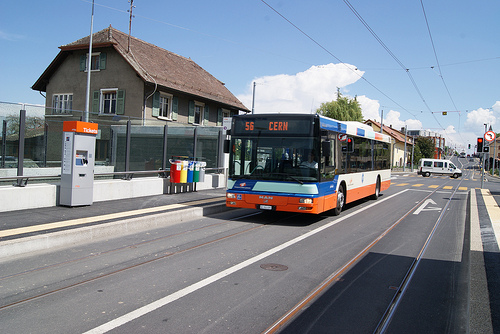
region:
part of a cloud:
[304, 50, 339, 92]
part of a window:
[277, 143, 292, 166]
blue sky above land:
[211, 13, 253, 50]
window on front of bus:
[228, 134, 325, 189]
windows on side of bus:
[336, 135, 394, 171]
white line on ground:
[222, 235, 299, 288]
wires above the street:
[323, 38, 458, 98]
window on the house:
[93, 78, 135, 122]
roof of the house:
[153, 65, 204, 87]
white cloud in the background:
[280, 68, 332, 95]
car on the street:
[411, 148, 467, 193]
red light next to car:
[469, 131, 494, 159]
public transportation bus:
[222, 81, 394, 216]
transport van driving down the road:
[412, 148, 466, 180]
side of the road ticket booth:
[61, 116, 103, 210]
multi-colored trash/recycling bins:
[167, 150, 210, 192]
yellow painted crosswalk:
[396, 178, 484, 193]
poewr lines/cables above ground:
[267, 3, 476, 147]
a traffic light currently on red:
[475, 134, 487, 158]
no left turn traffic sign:
[482, 127, 496, 144]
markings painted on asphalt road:
[412, 188, 452, 228]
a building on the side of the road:
[25, 14, 234, 151]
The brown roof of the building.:
[37, 31, 249, 113]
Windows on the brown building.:
[41, 84, 226, 127]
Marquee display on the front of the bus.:
[235, 115, 307, 132]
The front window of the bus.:
[230, 136, 320, 178]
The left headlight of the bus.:
[227, 190, 239, 202]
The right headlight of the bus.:
[291, 191, 316, 208]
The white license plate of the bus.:
[255, 205, 276, 213]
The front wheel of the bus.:
[335, 182, 349, 210]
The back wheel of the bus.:
[372, 173, 385, 200]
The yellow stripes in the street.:
[386, 168, 482, 200]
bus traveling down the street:
[225, 109, 398, 217]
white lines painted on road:
[107, 186, 463, 333]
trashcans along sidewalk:
[165, 158, 210, 184]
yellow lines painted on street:
[394, 174, 469, 192]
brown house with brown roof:
[40, 21, 244, 167]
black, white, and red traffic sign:
[484, 125, 495, 142]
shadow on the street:
[308, 243, 450, 333]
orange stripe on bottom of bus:
[215, 180, 391, 212]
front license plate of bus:
[257, 204, 277, 211]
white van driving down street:
[418, 153, 466, 178]